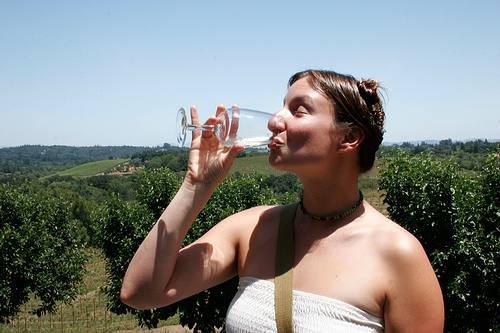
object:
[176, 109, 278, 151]
glass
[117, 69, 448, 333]
woman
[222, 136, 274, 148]
liquid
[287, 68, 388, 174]
hair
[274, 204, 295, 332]
strap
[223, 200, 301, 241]
shoulder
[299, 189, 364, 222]
necklace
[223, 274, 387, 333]
shirt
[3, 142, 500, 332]
tree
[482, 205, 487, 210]
leaves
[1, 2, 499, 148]
sky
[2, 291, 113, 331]
fence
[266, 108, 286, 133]
nose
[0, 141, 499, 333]
vineyard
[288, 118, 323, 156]
cheeks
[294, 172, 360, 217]
neck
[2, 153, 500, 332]
bushes